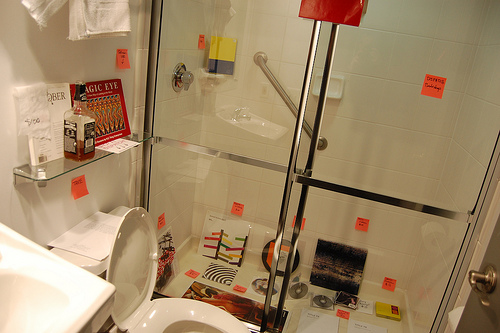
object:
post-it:
[71, 174, 90, 200]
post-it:
[419, 74, 447, 100]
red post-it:
[421, 73, 448, 98]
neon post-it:
[420, 73, 446, 99]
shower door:
[260, 0, 500, 333]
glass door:
[261, 3, 497, 333]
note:
[230, 201, 244, 216]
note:
[71, 174, 90, 200]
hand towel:
[20, 0, 69, 33]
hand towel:
[65, 0, 132, 42]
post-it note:
[231, 201, 245, 216]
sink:
[0, 222, 117, 333]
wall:
[0, 0, 500, 333]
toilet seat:
[124, 297, 257, 333]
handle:
[289, 173, 472, 223]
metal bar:
[258, 20, 322, 333]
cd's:
[312, 295, 333, 308]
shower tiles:
[317, 114, 452, 180]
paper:
[294, 308, 340, 333]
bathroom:
[0, 0, 498, 332]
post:
[355, 216, 370, 232]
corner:
[99, 281, 117, 299]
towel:
[64, 0, 133, 42]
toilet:
[50, 204, 256, 333]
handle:
[253, 51, 327, 150]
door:
[261, 0, 494, 333]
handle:
[468, 270, 493, 308]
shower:
[139, 0, 500, 333]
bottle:
[63, 82, 97, 162]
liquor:
[64, 140, 95, 162]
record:
[261, 239, 300, 277]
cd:
[312, 295, 333, 309]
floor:
[155, 248, 405, 333]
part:
[12, 289, 51, 325]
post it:
[381, 276, 396, 293]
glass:
[63, 80, 96, 163]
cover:
[266, 242, 290, 273]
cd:
[288, 282, 309, 299]